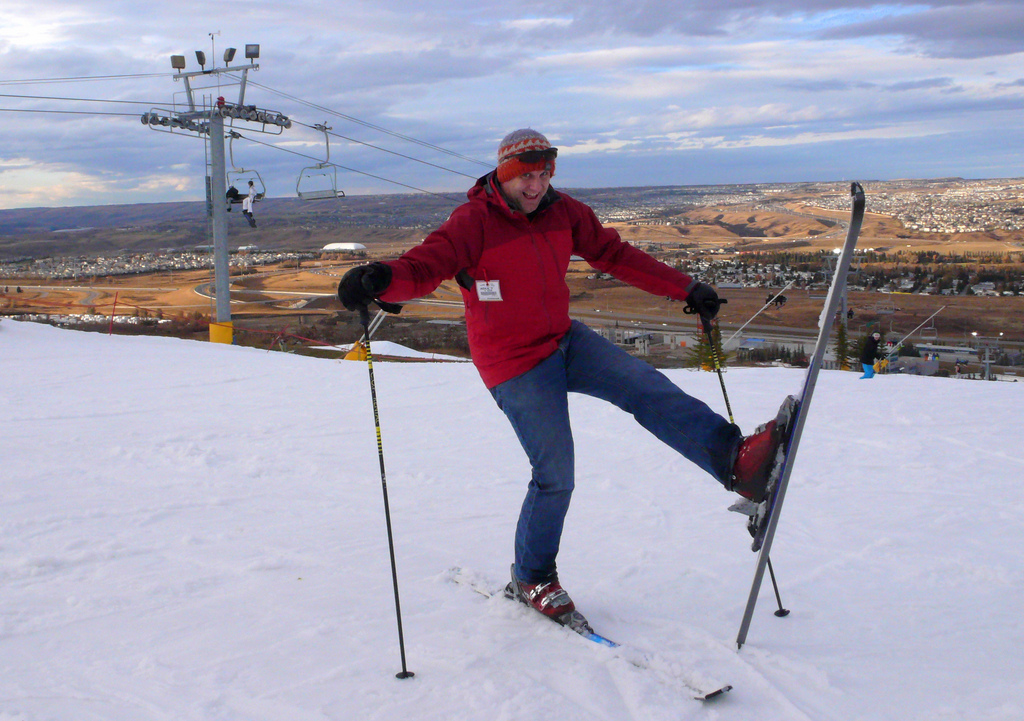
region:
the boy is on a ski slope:
[335, 126, 867, 700]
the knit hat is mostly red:
[493, 126, 558, 187]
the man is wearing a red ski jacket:
[369, 171, 693, 380]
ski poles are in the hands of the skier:
[334, 256, 799, 678]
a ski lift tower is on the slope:
[129, 38, 295, 380]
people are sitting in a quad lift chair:
[208, 168, 270, 222]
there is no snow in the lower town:
[8, 173, 1023, 415]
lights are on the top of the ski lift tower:
[136, 34, 298, 168]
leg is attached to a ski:
[580, 179, 866, 654]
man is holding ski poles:
[338, 124, 870, 681]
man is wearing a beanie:
[493, 124, 560, 213]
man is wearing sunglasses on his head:
[498, 126, 559, 216]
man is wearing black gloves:
[340, 126, 871, 687]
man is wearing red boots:
[340, 124, 868, 687]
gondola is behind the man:
[0, 25, 504, 343]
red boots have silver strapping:
[512, 565, 576, 620]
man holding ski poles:
[335, 126, 864, 690]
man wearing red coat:
[332, 127, 870, 701]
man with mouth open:
[487, 126, 563, 215]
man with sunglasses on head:
[490, 127, 561, 220]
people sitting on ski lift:
[215, 165, 272, 236]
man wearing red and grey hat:
[490, 124, 558, 216]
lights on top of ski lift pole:
[138, 37, 271, 345]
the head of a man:
[427, 94, 582, 227]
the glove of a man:
[330, 265, 395, 314]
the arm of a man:
[560, 219, 728, 327]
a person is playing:
[347, 112, 799, 648]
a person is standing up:
[344, 118, 791, 634]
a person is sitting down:
[239, 179, 262, 230]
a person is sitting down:
[218, 172, 234, 211]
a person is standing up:
[853, 317, 888, 388]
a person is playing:
[855, 317, 881, 381]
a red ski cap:
[501, 122, 562, 198]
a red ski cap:
[869, 321, 885, 337]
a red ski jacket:
[378, 175, 705, 384]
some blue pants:
[479, 321, 754, 588]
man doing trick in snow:
[283, 101, 815, 645]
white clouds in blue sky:
[35, 28, 90, 77]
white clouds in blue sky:
[58, 113, 101, 189]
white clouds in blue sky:
[17, 160, 60, 203]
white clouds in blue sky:
[371, 34, 426, 72]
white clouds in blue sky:
[561, 25, 663, 115]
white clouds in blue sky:
[626, 78, 678, 133]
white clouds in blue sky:
[740, 98, 810, 144]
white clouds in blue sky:
[822, 57, 903, 144]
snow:
[78, 487, 159, 568]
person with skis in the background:
[185, 66, 1018, 656]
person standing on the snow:
[292, 69, 986, 715]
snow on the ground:
[63, 328, 863, 706]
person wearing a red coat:
[278, 47, 889, 618]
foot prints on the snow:
[110, 332, 939, 712]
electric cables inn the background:
[88, 40, 439, 396]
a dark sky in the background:
[104, 13, 1005, 156]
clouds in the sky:
[46, 40, 843, 193]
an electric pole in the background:
[104, 43, 351, 404]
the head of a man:
[488, 138, 586, 216]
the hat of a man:
[491, 129, 552, 178]